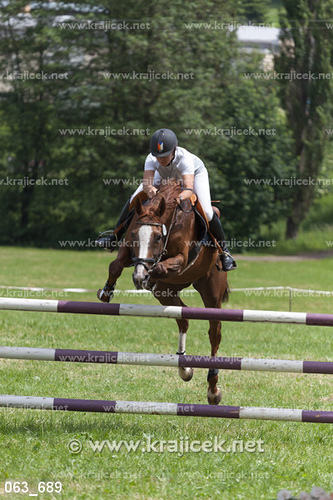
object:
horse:
[97, 174, 237, 403]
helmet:
[148, 128, 178, 158]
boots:
[207, 210, 237, 273]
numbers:
[3, 467, 53, 496]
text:
[8, 69, 77, 82]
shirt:
[144, 149, 209, 175]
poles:
[0, 389, 332, 426]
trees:
[1, 20, 48, 240]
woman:
[95, 127, 237, 274]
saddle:
[114, 185, 210, 239]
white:
[137, 224, 151, 279]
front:
[66, 33, 267, 406]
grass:
[0, 424, 332, 500]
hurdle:
[0, 294, 332, 426]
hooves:
[206, 371, 221, 406]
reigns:
[132, 187, 203, 290]